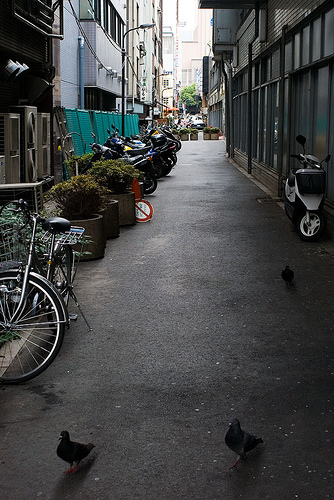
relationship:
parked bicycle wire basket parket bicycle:
[2, 214, 97, 378] [0, 198, 116, 399]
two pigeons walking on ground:
[40, 415, 292, 479] [50, 404, 330, 489]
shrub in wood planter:
[88, 159, 131, 194] [107, 189, 137, 220]